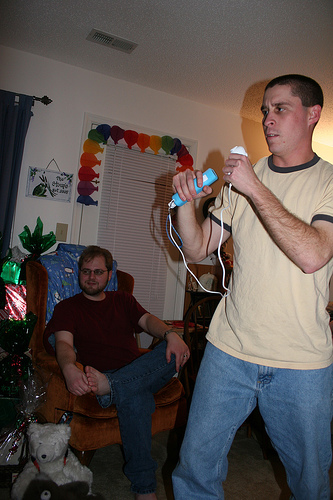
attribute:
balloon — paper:
[74, 165, 103, 181]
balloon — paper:
[134, 128, 148, 152]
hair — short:
[258, 66, 326, 110]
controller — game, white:
[226, 145, 250, 186]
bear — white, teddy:
[2, 412, 86, 474]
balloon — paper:
[79, 154, 101, 168]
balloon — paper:
[81, 181, 93, 201]